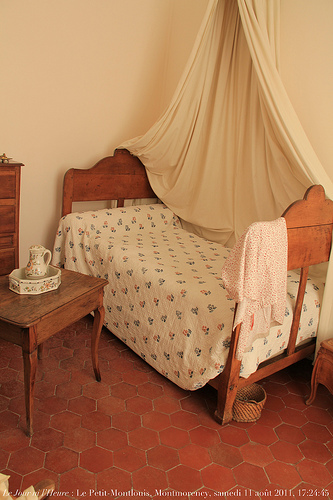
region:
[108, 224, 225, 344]
The bedding is vintage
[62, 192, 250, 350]
The bed has multiple colors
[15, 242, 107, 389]
The bed has a side table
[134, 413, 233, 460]
The bedroom has a floor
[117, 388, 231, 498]
The floor is brown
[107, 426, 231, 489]
The floor has shapes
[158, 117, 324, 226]
The bedroom has curtains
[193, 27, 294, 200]
The curtains are white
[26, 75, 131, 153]
The bedroom paint is white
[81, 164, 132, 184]
The bed is made out of wood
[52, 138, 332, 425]
A bed is in the room.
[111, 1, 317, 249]
A curtain is draped over the bed.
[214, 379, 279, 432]
A basket is under the bed.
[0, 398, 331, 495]
The floor is red.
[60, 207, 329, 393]
A sheet covers the bed.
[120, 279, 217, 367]
A flower pattern is on the sheet.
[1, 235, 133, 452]
A table is in the room.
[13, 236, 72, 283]
A pitcher is on the table.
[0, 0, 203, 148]
The wall is cream colored.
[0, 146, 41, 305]
A dresser is behind the table.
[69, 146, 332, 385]
a twin bed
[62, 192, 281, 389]
flower bed sheets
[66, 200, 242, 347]
white flowered bed sheets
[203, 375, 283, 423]
a wicker basket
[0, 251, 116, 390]
a wood table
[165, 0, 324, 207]
a white blanket hanging on the wall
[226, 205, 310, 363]
a pink blanket hanging off the bed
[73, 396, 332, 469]
maroon tile flooring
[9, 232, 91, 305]
a pitcher and bowl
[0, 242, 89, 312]
a pitcher and bowl on a wood table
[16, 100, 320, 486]
This is a picture of a bedroom.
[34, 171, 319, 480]
This picture is taken outside.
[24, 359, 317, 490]
Tiles are on the floor.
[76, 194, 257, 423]
The bedding has flowers on it.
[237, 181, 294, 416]
The bed frame is wood.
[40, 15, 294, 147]
The walls are light yellow.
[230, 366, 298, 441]
A basket is under the bed.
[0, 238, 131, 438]
A wood table is next to the bed.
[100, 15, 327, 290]
A beige piece of fabric hangs from the ceiling.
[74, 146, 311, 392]
The bedspread covers the bed.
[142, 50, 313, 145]
white draped cotton canopy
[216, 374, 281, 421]
wicker basket underneath bed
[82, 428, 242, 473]
red hexagonal shaped tile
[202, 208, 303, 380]
white and pink floral sheet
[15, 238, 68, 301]
white floral tea set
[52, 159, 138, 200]
wood designed headboard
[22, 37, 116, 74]
cream painted wall color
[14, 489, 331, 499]
white font text at bottom of photo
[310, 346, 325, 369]
small wooden end table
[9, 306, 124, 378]
above bed wooden table